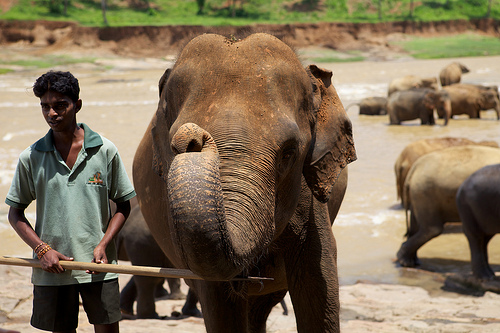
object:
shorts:
[31, 270, 133, 332]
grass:
[408, 31, 487, 61]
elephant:
[118, 30, 361, 332]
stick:
[171, 255, 275, 294]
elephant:
[386, 70, 439, 96]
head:
[158, 31, 346, 281]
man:
[8, 70, 137, 332]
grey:
[466, 180, 496, 209]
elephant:
[456, 163, 498, 290]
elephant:
[377, 89, 454, 129]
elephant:
[446, 83, 498, 122]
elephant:
[437, 62, 469, 85]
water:
[0, 56, 500, 294]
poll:
[0, 255, 277, 281]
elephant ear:
[300, 58, 359, 208]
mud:
[312, 70, 354, 211]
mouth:
[219, 243, 292, 297]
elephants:
[378, 84, 451, 124]